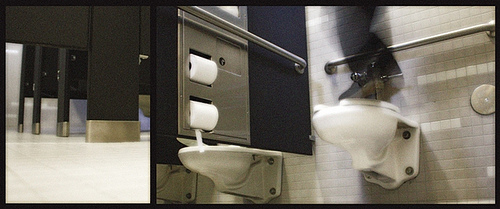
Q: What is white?
A: Floor.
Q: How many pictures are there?
A: Three.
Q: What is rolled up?
A: Toilet paper.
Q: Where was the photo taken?
A: In a bathroom.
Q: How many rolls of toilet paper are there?
A: Two.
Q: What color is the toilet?
A: White.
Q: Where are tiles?
A: On the wall.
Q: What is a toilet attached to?
A: The wall.